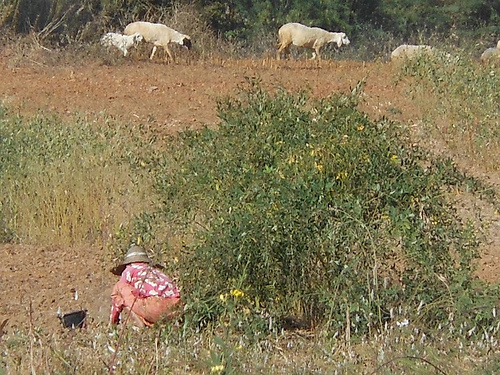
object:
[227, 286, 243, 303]
flower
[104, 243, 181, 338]
woman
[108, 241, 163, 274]
hat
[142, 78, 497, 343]
bush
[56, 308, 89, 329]
bucket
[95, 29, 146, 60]
sheep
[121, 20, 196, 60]
sheep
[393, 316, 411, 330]
flower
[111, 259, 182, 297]
scarf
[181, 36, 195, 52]
face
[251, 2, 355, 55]
trees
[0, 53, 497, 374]
ground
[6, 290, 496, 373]
grass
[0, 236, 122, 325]
dirt patch